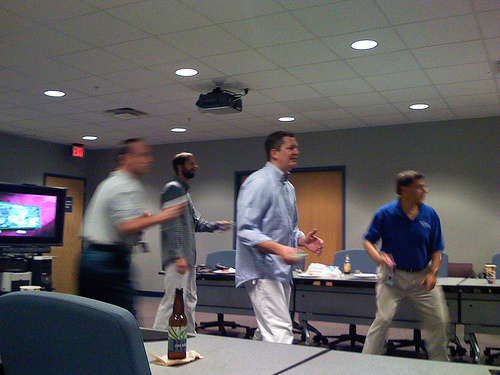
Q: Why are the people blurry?
A: They're moving.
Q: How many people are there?
A: Four.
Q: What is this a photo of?
A: People playing Wii.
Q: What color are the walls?
A: Grey.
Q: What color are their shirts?
A: Blue.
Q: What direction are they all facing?
A: Right.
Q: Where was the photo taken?
A: In a conference room.